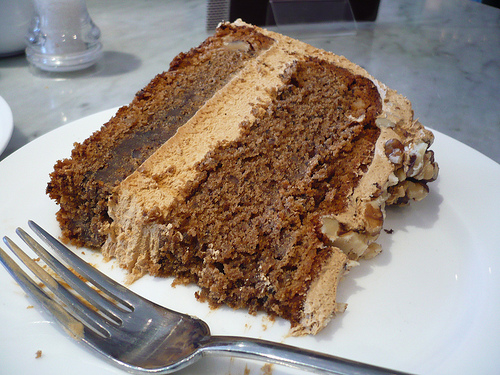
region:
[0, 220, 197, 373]
the fork is silver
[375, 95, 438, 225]
the icing is on the cake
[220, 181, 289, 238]
the cake is brown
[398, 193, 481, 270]
the plate is white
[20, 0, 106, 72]
the salt shaker is on the table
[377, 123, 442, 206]
the nuts are on the icing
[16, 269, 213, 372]
the fork is shiney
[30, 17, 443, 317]
a piece of cake is on the plate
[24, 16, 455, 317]
chocolate cake on white plate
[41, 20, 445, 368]
chocolate cake with chocolate frosting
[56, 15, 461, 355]
chocolate cake with walnut topping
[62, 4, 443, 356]
two layer chocolate cake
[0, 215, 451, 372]
metal fork on white place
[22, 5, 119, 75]
clear salt shaker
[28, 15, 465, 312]
slice of cake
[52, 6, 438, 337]
cake with two layers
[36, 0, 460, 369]
cake with chocolate mousse filling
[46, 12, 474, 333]
slice of cake on white plate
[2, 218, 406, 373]
A fork with cake smudges on it.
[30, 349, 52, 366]
A small cake crumb on a plate.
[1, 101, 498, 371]
A round white plate.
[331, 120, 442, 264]
Nuts on a piece of cake.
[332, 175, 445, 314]
A shadow of a piece of cake on a plate.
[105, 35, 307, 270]
Frosting in the middle of a piece of cake.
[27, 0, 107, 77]
A glass object.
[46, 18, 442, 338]
A tan and brown piece of cake.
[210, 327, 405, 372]
The handle on a fork.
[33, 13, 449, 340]
a slice of coffee and walnut cake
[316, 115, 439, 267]
walnuts on top of a cake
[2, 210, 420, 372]
stainless steel fork next to a slice of cake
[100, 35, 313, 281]
icing inside a slice of cake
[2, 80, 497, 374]
a white plate containing a piece of cake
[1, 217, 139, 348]
four prongs on a fork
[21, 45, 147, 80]
shadow of a container on a table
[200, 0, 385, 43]
a clear plastic document holder on a table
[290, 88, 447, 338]
frosting on top of a cake slice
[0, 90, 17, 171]
edge of a white saucer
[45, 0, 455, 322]
A piece of cake is on the plate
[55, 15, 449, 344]
The cake is brown and light brown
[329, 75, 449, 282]
The cake has nuts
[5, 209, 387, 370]
The stainless steel fork sits on the plate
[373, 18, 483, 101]
The table is made of marble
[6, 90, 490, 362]
The white plate has cake on it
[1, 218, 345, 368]
The fork is a silver color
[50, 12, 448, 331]
The slice of cake is on a plate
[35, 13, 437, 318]
A piece of cake is on a white plate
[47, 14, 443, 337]
Cake is served on a plate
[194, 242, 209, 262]
A piece of food.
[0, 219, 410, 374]
the fork is silver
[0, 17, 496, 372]
the fork is on the plate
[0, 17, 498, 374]
the slice of cake is on the plate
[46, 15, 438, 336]
the slice of cake is lying on its side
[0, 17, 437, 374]
the fork is next to the slice of cake